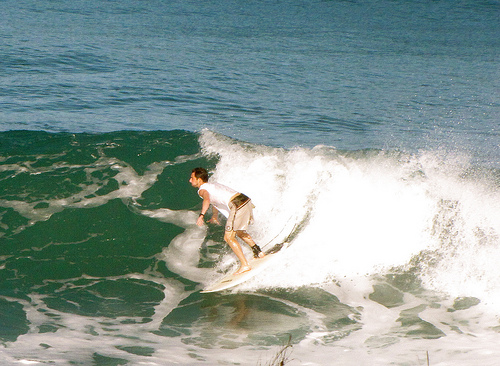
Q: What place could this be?
A: It is a sea.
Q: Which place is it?
A: It is a sea.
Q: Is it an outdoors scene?
A: Yes, it is outdoors.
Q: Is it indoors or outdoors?
A: It is outdoors.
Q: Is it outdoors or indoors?
A: It is outdoors.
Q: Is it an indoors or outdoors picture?
A: It is outdoors.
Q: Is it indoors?
A: No, it is outdoors.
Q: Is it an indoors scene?
A: No, it is outdoors.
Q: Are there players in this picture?
A: No, there are no players.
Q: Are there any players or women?
A: No, there are no players or women.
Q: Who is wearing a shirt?
A: The man is wearing a shirt.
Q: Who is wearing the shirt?
A: The man is wearing a shirt.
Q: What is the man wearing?
A: The man is wearing a shirt.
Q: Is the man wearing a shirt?
A: Yes, the man is wearing a shirt.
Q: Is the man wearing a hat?
A: No, the man is wearing a shirt.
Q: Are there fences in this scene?
A: No, there are no fences.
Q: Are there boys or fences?
A: No, there are no fences or boys.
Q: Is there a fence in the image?
A: No, there are no fences.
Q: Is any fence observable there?
A: No, there are no fences.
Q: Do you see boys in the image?
A: No, there are no boys.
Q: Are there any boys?
A: No, there are no boys.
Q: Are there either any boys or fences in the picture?
A: No, there are no boys or fences.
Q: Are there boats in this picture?
A: No, there are no boats.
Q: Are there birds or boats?
A: No, there are no boats or birds.